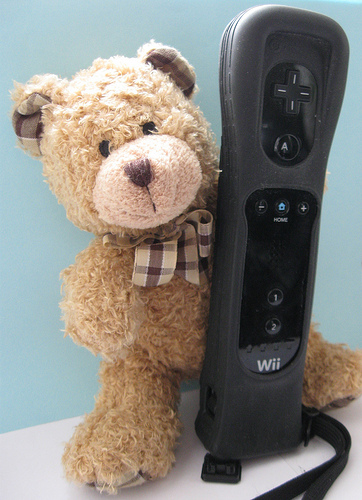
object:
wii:
[193, 4, 351, 462]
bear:
[9, 39, 361, 498]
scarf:
[102, 208, 214, 286]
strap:
[250, 401, 351, 499]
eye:
[99, 138, 112, 159]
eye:
[141, 121, 160, 135]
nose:
[123, 156, 154, 187]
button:
[265, 318, 283, 334]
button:
[267, 288, 283, 306]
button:
[254, 199, 269, 215]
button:
[273, 198, 290, 214]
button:
[298, 202, 309, 214]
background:
[0, 0, 361, 436]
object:
[0, 388, 362, 500]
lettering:
[257, 356, 281, 373]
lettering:
[273, 216, 289, 223]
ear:
[138, 38, 198, 101]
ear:
[8, 71, 66, 161]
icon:
[278, 202, 285, 211]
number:
[273, 294, 278, 304]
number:
[271, 323, 277, 333]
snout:
[93, 134, 203, 229]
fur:
[8, 37, 360, 494]